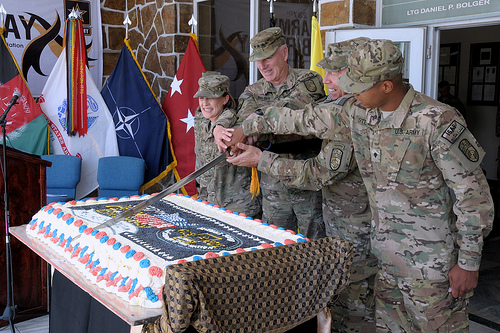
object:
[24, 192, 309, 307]
cake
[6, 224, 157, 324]
table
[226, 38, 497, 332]
man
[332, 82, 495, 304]
uniform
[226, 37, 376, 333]
soldier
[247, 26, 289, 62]
hat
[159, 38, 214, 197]
flags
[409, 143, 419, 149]
green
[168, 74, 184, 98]
stars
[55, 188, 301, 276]
large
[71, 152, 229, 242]
sword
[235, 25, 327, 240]
men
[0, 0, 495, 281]
daytime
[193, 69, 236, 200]
woman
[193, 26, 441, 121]
four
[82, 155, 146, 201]
chair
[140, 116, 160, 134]
blue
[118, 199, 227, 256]
military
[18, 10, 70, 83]
sign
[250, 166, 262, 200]
tassel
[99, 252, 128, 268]
white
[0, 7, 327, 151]
row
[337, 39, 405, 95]
cap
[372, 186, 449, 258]
camoflauge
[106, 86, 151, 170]
emblem